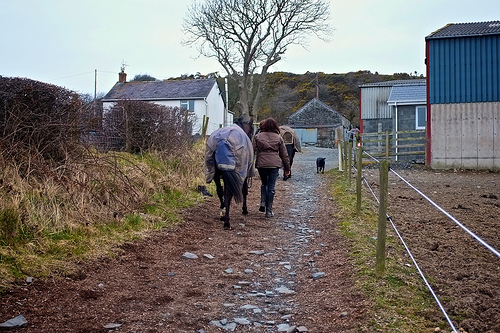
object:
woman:
[251, 118, 289, 217]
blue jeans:
[259, 169, 280, 193]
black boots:
[267, 193, 275, 217]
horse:
[203, 117, 257, 230]